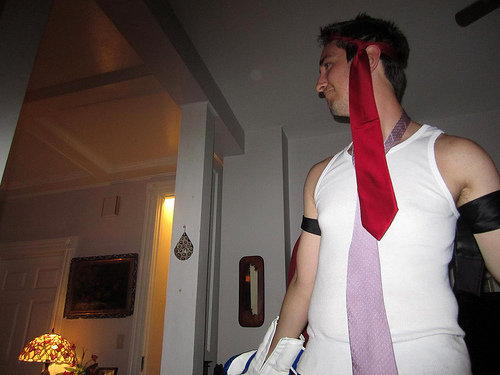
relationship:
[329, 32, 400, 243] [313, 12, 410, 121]
tie around head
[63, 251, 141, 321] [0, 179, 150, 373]
painting on wall